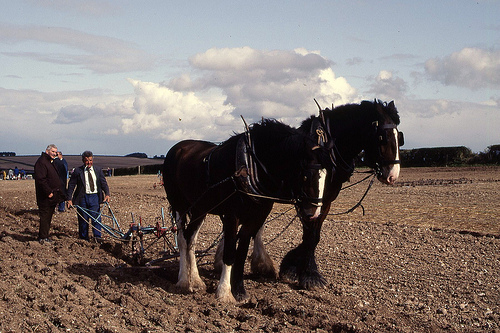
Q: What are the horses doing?
A: Plowing.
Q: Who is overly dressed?
A: The farmer.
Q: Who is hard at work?
A: Clydesdales.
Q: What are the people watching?
A: The plowing.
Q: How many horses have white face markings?
A: Two.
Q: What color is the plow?
A: Blue.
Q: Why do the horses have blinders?
A: For focus.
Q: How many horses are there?
A: Two.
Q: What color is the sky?
A: Blue.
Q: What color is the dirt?
A: Brown.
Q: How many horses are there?
A: 2.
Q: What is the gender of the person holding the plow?
A: Male.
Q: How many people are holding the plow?
A: 1.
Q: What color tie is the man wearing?
A: Red.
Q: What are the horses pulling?
A: Plow.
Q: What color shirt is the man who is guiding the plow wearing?
A: White.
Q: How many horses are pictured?
A: Two.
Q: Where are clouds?
A: In the sky.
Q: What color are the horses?
A: Dark brown and white.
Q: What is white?
A: Clouds.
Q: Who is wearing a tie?
A: One man.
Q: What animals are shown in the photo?
A: Horses.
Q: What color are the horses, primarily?
A: Brown.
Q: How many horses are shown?
A: Two.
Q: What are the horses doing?
A: Pulling a plough.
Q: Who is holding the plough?
A: The man in the tie.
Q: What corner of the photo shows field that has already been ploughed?
A: Bottom left.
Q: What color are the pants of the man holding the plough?
A: Blue.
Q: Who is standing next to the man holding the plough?
A: The man dressed in brown.